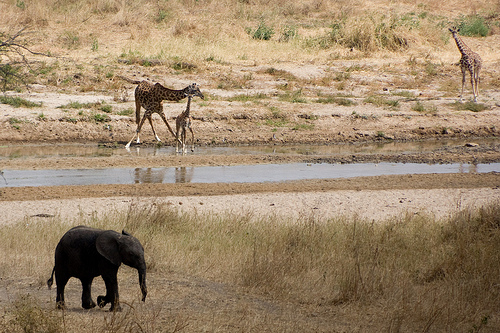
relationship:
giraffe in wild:
[124, 78, 205, 154] [4, 4, 498, 326]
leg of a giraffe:
[131, 110, 153, 147] [126, 80, 203, 152]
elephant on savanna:
[45, 224, 149, 314] [2, 130, 499, 325]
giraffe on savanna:
[125, 68, 205, 157] [3, 0, 483, 140]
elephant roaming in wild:
[54, 216, 160, 324] [3, 22, 490, 317]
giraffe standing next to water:
[444, 23, 486, 100] [1, 140, 484, 184]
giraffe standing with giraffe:
[124, 78, 205, 154] [124, 78, 205, 154]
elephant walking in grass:
[45, 224, 149, 314] [4, 221, 498, 327]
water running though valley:
[0, 156, 497, 190] [2, 0, 499, 330]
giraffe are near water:
[124, 78, 205, 154] [1, 140, 484, 184]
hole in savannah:
[0, 126, 497, 193] [3, 5, 497, 327]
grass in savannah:
[201, 203, 498, 328] [3, 5, 497, 327]